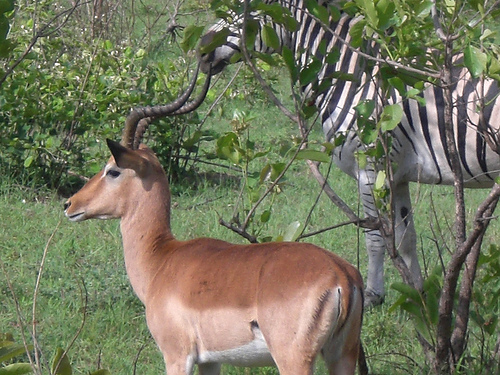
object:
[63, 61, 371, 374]
gazelle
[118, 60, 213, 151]
horns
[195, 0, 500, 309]
zebra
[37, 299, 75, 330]
grass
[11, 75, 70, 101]
leaves